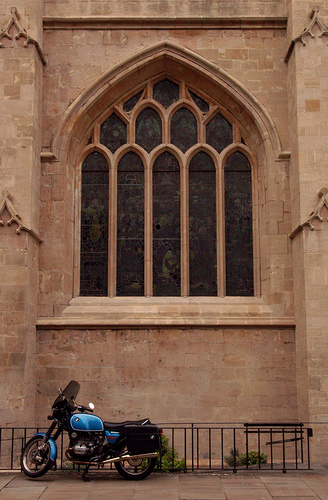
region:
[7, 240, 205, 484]
a motorcycle parked in front of a church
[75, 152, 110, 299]
a stained glass window of a church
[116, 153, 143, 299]
a stained glass window of a church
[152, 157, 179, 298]
a stained glass window of a church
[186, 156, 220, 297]
a stained glass window of a church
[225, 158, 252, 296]
a stained glass window of a church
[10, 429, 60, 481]
the front wheel of a motorcycle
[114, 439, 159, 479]
the rear wheel of a motorcycle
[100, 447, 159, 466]
the muffler of a motorcycle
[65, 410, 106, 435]
the gas tank of a motorcycle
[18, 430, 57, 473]
wheel of a bike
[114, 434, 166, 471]
back wheel of a bike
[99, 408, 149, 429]
seat of a bike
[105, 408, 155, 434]
black seat of a bike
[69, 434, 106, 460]
engine of a bike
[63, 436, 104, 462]
an engine of a bike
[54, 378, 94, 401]
window of a bike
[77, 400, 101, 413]
handle of a bike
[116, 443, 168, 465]
exhaust of a bike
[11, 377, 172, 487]
a parked motorbike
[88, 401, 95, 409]
mirror on the side of the bike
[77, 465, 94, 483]
kickstand is down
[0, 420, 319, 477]
small black fence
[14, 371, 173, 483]
black and blue motorbike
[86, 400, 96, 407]
light shining on the mirror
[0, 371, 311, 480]
motorbike next to a fence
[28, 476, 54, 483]
shadow on the ground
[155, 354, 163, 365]
dark spot on the wall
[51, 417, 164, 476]
motorcycle on the fence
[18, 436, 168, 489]
the motorcycle is parked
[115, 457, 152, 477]
wheel of the motorcycle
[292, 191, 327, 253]
decoration on the building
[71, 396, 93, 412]
mirror on the motorcycle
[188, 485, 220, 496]
the ground is brick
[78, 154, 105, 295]
part of stained glass window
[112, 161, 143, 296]
part of stained glass window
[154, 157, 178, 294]
part of stained glass window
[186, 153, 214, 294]
part of stained glass window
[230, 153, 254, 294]
part of stained glass window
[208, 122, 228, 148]
part of stained glass window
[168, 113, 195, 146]
part of stained glass window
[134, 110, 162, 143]
part of stained glass window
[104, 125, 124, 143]
part of stained glass window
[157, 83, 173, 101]
part of stained glass window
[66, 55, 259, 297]
the stunning large arched window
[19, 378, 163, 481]
blue and black motorcycle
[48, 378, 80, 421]
motorcycle has face shield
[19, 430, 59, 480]
front wheel of motorcycle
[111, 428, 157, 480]
back wheel of motorcycle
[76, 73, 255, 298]
large window on brick wall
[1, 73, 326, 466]
large, brick wall with window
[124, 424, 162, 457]
black box on motorcycle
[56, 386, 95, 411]
motorcycle has two mirrors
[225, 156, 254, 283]
a window on the building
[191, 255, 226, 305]
a window on the building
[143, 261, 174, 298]
a window on the building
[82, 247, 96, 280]
a window on the building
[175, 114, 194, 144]
a window on the building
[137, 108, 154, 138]
a window on the building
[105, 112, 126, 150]
a window on the building